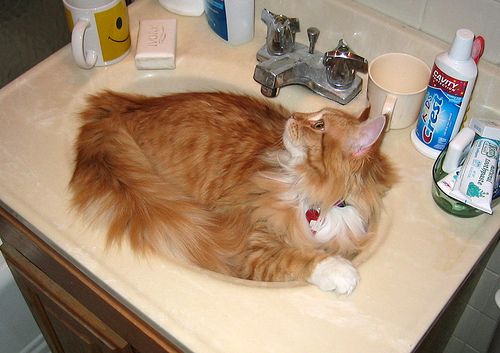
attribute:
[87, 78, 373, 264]
cat — brown, orange, fluffy, looking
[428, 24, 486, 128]
tooth paste — white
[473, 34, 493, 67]
toothbrush — red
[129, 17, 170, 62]
soap — bar, wrapped, white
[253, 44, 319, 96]
tap — metal, silver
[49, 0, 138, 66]
mug — yellow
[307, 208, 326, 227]
item — red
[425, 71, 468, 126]
label — red